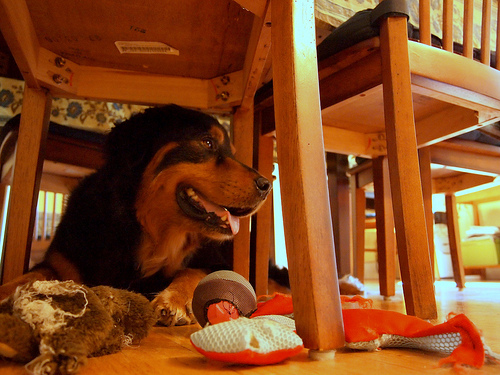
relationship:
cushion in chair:
[245, 3, 486, 110] [232, 5, 488, 325]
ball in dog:
[191, 269, 259, 327] [6, 101, 368, 326]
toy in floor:
[193, 301, 498, 369] [3, 276, 495, 373]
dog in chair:
[0, 103, 284, 328] [0, 0, 349, 362]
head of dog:
[98, 101, 269, 243] [0, 103, 284, 328]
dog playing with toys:
[54, 100, 284, 299] [11, 262, 479, 356]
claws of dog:
[3, 268, 222, 349] [20, 55, 298, 320]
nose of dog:
[253, 175, 273, 199] [8, 97, 281, 317]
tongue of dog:
[194, 190, 240, 235] [1, 100, 271, 326]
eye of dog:
[198, 135, 213, 148] [6, 101, 368, 326]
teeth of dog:
[179, 182, 241, 235] [0, 103, 284, 328]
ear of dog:
[99, 103, 186, 157] [31, 94, 301, 318]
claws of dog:
[149, 300, 197, 328] [31, 100, 277, 312]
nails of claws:
[154, 298, 174, 323] [149, 300, 197, 328]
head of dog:
[98, 101, 269, 243] [6, 101, 368, 326]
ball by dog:
[191, 269, 259, 327] [6, 101, 368, 326]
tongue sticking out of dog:
[224, 205, 243, 236] [73, 72, 309, 337]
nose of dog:
[253, 176, 273, 194] [54, 97, 272, 272]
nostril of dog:
[258, 181, 271, 197] [1, 100, 271, 326]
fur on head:
[100, 103, 212, 215] [98, 101, 269, 243]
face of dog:
[129, 112, 281, 247] [75, 110, 261, 258]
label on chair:
[115, 40, 179, 57] [1, 1, 273, 300]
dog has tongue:
[0, 103, 284, 328] [199, 198, 244, 236]